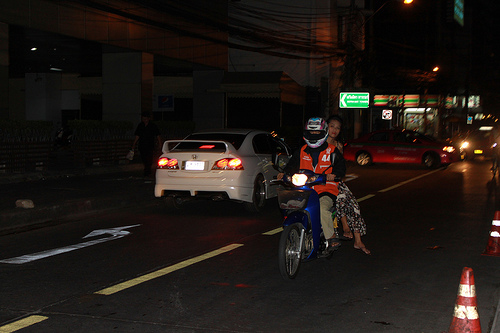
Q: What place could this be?
A: It is a road.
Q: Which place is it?
A: It is a road.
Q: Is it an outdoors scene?
A: Yes, it is outdoors.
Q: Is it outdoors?
A: Yes, it is outdoors.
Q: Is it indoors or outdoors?
A: It is outdoors.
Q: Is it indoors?
A: No, it is outdoors.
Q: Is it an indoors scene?
A: No, it is outdoors.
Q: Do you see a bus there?
A: No, there are no buses.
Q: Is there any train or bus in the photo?
A: No, there are no buses or trains.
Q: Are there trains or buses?
A: No, there are no buses or trains.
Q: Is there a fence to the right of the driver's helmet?
A: No, there is a passenger to the right of the helmet.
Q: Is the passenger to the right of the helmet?
A: Yes, the passenger is to the right of the helmet.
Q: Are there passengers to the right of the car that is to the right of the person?
A: Yes, there is a passenger to the right of the car.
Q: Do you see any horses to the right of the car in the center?
A: No, there is a passenger to the right of the car.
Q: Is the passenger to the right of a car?
A: Yes, the passenger is to the right of a car.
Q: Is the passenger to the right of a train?
A: No, the passenger is to the right of a car.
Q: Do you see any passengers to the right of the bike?
A: Yes, there is a passenger to the right of the bike.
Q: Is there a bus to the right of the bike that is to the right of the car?
A: No, there is a passenger to the right of the bike.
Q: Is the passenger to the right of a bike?
A: Yes, the passenger is to the right of a bike.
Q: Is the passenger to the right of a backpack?
A: No, the passenger is to the right of a bike.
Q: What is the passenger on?
A: The passenger is on the bike.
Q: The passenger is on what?
A: The passenger is on the bike.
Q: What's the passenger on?
A: The passenger is on the bike.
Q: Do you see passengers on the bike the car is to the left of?
A: Yes, there is a passenger on the bike.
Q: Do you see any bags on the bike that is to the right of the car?
A: No, there is a passenger on the bike.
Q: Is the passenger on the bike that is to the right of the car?
A: Yes, the passenger is on the bike.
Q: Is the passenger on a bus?
A: No, the passenger is on the bike.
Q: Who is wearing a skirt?
A: The passenger is wearing a skirt.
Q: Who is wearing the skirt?
A: The passenger is wearing a skirt.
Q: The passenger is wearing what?
A: The passenger is wearing a skirt.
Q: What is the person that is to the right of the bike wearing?
A: The passenger is wearing a skirt.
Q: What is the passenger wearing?
A: The passenger is wearing a skirt.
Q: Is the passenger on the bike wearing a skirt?
A: Yes, the passenger is wearing a skirt.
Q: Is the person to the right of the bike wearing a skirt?
A: Yes, the passenger is wearing a skirt.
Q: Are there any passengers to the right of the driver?
A: Yes, there is a passenger to the right of the driver.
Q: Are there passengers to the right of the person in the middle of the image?
A: Yes, there is a passenger to the right of the driver.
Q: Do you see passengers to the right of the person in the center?
A: Yes, there is a passenger to the right of the driver.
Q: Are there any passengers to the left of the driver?
A: No, the passenger is to the right of the driver.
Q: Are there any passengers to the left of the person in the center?
A: No, the passenger is to the right of the driver.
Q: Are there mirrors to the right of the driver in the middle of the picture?
A: No, there is a passenger to the right of the driver.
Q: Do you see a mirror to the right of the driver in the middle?
A: No, there is a passenger to the right of the driver.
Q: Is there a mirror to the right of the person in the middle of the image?
A: No, there is a passenger to the right of the driver.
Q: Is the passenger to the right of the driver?
A: Yes, the passenger is to the right of the driver.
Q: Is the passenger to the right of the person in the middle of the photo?
A: Yes, the passenger is to the right of the driver.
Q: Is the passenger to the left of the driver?
A: No, the passenger is to the right of the driver.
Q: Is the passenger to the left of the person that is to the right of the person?
A: No, the passenger is to the right of the driver.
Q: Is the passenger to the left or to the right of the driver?
A: The passenger is to the right of the driver.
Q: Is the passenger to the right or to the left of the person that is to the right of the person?
A: The passenger is to the right of the driver.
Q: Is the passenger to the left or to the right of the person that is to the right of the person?
A: The passenger is to the right of the driver.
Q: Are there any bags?
A: No, there are no bags.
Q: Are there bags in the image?
A: No, there are no bags.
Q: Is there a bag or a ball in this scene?
A: No, there are no bags or balls.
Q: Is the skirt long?
A: Yes, the skirt is long.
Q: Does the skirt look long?
A: Yes, the skirt is long.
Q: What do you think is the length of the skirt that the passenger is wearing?
A: The skirt is long.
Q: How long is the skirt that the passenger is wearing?
A: The skirt is long.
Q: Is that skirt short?
A: No, the skirt is long.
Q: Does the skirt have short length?
A: No, the skirt is long.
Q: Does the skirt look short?
A: No, the skirt is long.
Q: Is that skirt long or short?
A: The skirt is long.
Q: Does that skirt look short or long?
A: The skirt is long.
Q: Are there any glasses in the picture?
A: No, there are no glasses.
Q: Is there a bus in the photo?
A: No, there are no buses.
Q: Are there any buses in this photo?
A: No, there are no buses.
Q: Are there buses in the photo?
A: No, there are no buses.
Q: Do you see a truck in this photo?
A: No, there are no trucks.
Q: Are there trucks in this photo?
A: No, there are no trucks.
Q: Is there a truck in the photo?
A: No, there are no trucks.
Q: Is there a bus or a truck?
A: No, there are no trucks or buses.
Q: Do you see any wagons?
A: No, there are no wagons.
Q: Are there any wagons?
A: No, there are no wagons.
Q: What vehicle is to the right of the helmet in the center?
A: The vehicle is a car.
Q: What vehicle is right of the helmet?
A: The vehicle is a car.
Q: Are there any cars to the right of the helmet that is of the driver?
A: Yes, there is a car to the right of the helmet.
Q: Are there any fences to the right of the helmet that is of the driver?
A: No, there is a car to the right of the helmet.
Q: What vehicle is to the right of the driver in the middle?
A: The vehicle is a car.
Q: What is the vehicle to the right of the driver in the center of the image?
A: The vehicle is a car.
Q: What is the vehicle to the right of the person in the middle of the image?
A: The vehicle is a car.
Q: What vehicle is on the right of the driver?
A: The vehicle is a car.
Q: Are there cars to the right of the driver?
A: Yes, there is a car to the right of the driver.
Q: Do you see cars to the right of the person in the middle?
A: Yes, there is a car to the right of the driver.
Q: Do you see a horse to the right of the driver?
A: No, there is a car to the right of the driver.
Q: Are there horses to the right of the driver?
A: No, there is a car to the right of the driver.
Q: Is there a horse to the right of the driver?
A: No, there is a car to the right of the driver.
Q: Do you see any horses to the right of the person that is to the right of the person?
A: No, there is a car to the right of the driver.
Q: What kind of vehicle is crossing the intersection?
A: The vehicle is a car.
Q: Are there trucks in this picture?
A: No, there are no trucks.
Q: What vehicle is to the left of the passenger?
A: The vehicle is a car.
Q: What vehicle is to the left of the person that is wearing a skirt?
A: The vehicle is a car.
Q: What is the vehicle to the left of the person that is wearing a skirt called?
A: The vehicle is a car.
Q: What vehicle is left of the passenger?
A: The vehicle is a car.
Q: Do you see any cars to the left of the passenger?
A: Yes, there is a car to the left of the passenger.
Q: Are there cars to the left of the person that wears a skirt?
A: Yes, there is a car to the left of the passenger.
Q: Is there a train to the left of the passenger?
A: No, there is a car to the left of the passenger.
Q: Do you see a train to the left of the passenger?
A: No, there is a car to the left of the passenger.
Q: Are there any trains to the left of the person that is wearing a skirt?
A: No, there is a car to the left of the passenger.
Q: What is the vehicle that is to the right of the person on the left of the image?
A: The vehicle is a car.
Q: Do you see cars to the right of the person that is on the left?
A: Yes, there is a car to the right of the person.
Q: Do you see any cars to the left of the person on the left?
A: No, the car is to the right of the person.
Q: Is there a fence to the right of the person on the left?
A: No, there is a car to the right of the person.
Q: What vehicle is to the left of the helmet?
A: The vehicle is a car.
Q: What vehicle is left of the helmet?
A: The vehicle is a car.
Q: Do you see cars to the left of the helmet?
A: Yes, there is a car to the left of the helmet.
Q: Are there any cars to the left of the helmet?
A: Yes, there is a car to the left of the helmet.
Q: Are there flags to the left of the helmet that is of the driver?
A: No, there is a car to the left of the helmet.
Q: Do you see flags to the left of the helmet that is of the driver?
A: No, there is a car to the left of the helmet.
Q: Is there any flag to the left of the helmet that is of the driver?
A: No, there is a car to the left of the helmet.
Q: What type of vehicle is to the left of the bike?
A: The vehicle is a car.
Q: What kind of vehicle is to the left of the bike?
A: The vehicle is a car.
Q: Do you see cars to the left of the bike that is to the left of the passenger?
A: Yes, there is a car to the left of the bike.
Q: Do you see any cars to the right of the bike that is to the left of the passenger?
A: No, the car is to the left of the bike.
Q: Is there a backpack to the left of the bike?
A: No, there is a car to the left of the bike.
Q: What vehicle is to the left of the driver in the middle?
A: The vehicle is a car.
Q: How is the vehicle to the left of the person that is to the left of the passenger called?
A: The vehicle is a car.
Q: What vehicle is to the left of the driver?
A: The vehicle is a car.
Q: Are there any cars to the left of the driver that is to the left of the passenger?
A: Yes, there is a car to the left of the driver.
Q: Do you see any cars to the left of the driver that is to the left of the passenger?
A: Yes, there is a car to the left of the driver.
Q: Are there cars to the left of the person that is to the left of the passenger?
A: Yes, there is a car to the left of the driver.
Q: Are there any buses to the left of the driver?
A: No, there is a car to the left of the driver.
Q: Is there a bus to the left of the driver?
A: No, there is a car to the left of the driver.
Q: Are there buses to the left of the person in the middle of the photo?
A: No, there is a car to the left of the driver.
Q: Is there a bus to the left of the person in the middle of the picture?
A: No, there is a car to the left of the driver.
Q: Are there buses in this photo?
A: No, there are no buses.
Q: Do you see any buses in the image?
A: No, there are no buses.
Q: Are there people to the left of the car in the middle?
A: Yes, there is a person to the left of the car.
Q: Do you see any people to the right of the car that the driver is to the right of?
A: No, the person is to the left of the car.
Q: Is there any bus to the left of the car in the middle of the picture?
A: No, there is a person to the left of the car.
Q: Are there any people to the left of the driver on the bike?
A: Yes, there is a person to the left of the driver.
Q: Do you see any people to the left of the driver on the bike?
A: Yes, there is a person to the left of the driver.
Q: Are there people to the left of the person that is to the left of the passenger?
A: Yes, there is a person to the left of the driver.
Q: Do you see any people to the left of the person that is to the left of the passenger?
A: Yes, there is a person to the left of the driver.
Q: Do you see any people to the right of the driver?
A: No, the person is to the left of the driver.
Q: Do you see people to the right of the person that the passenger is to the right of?
A: No, the person is to the left of the driver.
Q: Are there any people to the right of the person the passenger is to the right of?
A: No, the person is to the left of the driver.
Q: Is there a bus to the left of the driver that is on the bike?
A: No, there is a person to the left of the driver.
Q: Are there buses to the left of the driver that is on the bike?
A: No, there is a person to the left of the driver.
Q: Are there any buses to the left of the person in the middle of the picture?
A: No, there is a person to the left of the driver.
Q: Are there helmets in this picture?
A: Yes, there is a helmet.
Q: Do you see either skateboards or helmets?
A: Yes, there is a helmet.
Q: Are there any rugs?
A: No, there are no rugs.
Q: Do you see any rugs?
A: No, there are no rugs.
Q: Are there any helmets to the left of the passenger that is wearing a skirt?
A: Yes, there is a helmet to the left of the passenger.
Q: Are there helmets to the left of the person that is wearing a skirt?
A: Yes, there is a helmet to the left of the passenger.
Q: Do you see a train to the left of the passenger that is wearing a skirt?
A: No, there is a helmet to the left of the passenger.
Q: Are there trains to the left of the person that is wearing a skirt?
A: No, there is a helmet to the left of the passenger.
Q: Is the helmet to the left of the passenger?
A: Yes, the helmet is to the left of the passenger.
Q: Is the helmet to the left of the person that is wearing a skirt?
A: Yes, the helmet is to the left of the passenger.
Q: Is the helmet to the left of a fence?
A: No, the helmet is to the left of the passenger.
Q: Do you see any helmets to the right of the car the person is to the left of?
A: Yes, there is a helmet to the right of the car.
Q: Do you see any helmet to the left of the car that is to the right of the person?
A: No, the helmet is to the right of the car.